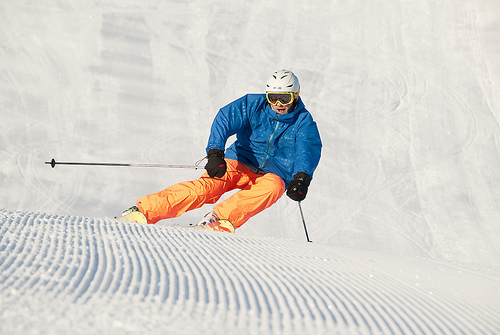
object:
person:
[113, 68, 330, 235]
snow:
[0, 0, 500, 335]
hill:
[0, 0, 500, 260]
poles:
[40, 154, 199, 170]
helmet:
[263, 66, 302, 94]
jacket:
[202, 91, 328, 190]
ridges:
[96, 235, 113, 292]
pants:
[137, 155, 291, 230]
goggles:
[263, 89, 295, 106]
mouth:
[276, 107, 286, 114]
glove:
[202, 148, 229, 180]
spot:
[217, 162, 225, 168]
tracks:
[106, 224, 118, 270]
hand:
[204, 148, 229, 179]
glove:
[286, 171, 312, 202]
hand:
[286, 171, 313, 202]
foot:
[117, 198, 152, 223]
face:
[264, 86, 297, 115]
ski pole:
[296, 202, 315, 243]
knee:
[195, 174, 225, 201]